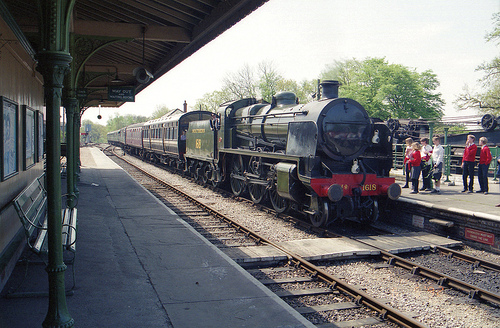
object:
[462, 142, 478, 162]
shirt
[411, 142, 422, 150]
hair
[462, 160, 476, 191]
pants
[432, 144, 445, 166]
shirt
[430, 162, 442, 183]
shorts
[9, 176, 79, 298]
bench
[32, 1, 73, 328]
poles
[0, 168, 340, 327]
shade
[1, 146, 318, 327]
platform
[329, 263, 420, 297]
pebbles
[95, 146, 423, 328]
tracks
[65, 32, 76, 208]
pole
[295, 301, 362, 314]
slats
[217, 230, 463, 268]
walkway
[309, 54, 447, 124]
tree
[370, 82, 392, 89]
leaves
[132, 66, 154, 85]
light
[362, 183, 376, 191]
number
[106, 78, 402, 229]
train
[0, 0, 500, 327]
station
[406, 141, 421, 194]
people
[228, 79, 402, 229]
engine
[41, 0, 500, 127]
sky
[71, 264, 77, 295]
leg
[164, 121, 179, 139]
windows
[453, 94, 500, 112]
limbs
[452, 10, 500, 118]
tree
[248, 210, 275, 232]
gravel